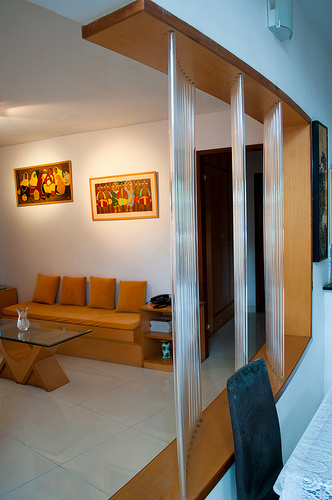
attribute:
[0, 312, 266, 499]
matting — white, tiled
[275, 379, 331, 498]
tablecloth — small, lace, white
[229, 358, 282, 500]
chair — black, velvet, dark blue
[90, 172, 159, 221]
picture — framed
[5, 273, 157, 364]
couch — orange, yellow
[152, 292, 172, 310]
phone — land line, black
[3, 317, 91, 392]
coffee table — glass, wood, wooden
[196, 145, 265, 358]
frame — wood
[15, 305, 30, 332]
vase — crystal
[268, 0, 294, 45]
fire alarm — electronic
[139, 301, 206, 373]
side table — wooden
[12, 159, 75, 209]
picture — framed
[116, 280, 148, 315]
pillow — orange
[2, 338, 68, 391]
base — wooden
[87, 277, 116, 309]
pillow — orange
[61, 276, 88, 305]
pillow — orange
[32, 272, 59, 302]
pillow — orange